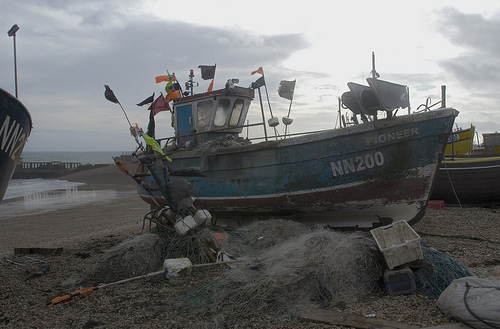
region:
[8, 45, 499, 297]
boats are pulled up onto the beach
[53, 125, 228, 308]
flag poles are on styrofoam buoys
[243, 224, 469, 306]
nets are in piles on the beach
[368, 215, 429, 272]
a plastic basket is on the nets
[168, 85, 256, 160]
the pilot house on the boat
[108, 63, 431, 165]
flag buoys are on the boat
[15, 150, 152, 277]
the ocean is at low tide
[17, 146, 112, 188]
a fence structure is on the beach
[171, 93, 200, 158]
the door is blue on the boat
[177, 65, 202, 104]
a light is on the top of the boat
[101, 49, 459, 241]
a shipwrecked boat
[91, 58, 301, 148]
numerous colored flags on the boat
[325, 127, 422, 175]
white lettering on the side of the boat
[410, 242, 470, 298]
tangled blue netting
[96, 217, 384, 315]
piles of dead seaweed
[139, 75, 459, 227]
blue red and white boat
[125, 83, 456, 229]
old dirty boat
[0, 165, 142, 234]
sandy beach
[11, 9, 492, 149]
grey stormy sky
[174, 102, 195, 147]
bright blue door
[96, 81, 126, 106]
THIS IS A FLAG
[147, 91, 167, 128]
THIS IS A FLAG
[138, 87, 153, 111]
THIS IS A FLAG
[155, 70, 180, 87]
THIS IS A FLAG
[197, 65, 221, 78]
THIS IS A FLAG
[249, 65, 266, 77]
THIS IS A FLAG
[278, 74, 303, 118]
THIS IS A FLAG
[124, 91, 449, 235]
THIS IS A BOAT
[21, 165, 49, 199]
THIS IS CALM WATER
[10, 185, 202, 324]
sandy shore of beach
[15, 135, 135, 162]
calm ocean in the background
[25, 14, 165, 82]
clouds floating in the sky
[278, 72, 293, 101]
small flag on boat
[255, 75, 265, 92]
small flag on boat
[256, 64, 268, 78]
small flag on boat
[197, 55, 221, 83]
small flag on boat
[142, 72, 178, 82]
small flag on boat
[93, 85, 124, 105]
small flag on boat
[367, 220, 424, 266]
white plastic bin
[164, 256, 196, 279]
a large rock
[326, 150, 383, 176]
white lettering on a boat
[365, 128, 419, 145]
white lettering on a boat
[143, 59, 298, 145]
flags are on a boat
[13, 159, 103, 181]
a dock in the distance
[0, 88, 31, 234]
side of a black boat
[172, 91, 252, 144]
cockpit of a boat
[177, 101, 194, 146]
door on a boat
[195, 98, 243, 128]
windows on a boat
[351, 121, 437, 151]
name on the boat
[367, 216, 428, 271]
empty crate near the front of boat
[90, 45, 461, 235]
a boat with a lot of flags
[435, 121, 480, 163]
a yellow boat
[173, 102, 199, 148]
blue door on the boat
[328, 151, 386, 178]
White NN200 on a boat side.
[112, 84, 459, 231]
Mostly blue boat with white top.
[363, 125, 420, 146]
White dirty word PIONEER on a boat side.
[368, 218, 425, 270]
A white empty bin by the boat front.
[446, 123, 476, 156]
A yellow boat front.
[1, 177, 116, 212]
Water coming to shore on the beach.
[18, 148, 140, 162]
Larger grey body of water past a smaller one.